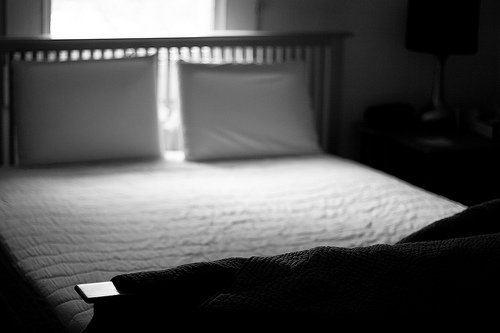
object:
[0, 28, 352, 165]
headboard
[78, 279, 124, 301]
footboard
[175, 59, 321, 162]
pillow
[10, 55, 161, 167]
pillow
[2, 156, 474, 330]
comforter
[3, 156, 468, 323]
sheet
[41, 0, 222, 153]
window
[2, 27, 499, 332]
bed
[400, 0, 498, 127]
lamp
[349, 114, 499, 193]
table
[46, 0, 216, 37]
light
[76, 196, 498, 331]
blanket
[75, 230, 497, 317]
footboard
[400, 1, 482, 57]
shade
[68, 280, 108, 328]
conner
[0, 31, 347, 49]
slat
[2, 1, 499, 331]
room